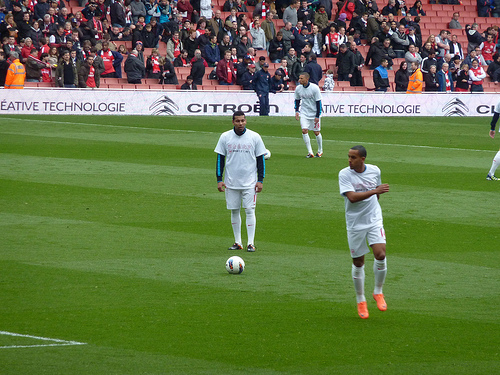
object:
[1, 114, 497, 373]
ground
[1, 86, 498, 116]
boundary board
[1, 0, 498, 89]
chairs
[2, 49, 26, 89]
guards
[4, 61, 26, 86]
dress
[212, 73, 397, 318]
soccer players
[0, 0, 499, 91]
crowd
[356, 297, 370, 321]
cleat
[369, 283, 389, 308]
cleat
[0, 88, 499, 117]
advertisements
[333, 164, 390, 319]
uniform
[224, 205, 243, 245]
leg sleeve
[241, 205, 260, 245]
leg sleeve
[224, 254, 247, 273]
ball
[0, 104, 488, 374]
scene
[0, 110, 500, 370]
pitch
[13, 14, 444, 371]
weather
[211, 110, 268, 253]
man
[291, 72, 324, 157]
man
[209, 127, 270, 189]
shirt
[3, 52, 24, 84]
man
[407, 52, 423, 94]
man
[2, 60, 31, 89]
coat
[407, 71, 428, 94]
coat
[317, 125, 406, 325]
man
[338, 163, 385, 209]
shirt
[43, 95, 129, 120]
word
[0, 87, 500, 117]
wall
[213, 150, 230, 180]
stripes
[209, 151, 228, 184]
shirt sleeve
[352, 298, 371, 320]
shoe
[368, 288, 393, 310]
shoe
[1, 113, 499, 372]
grass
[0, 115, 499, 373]
field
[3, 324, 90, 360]
lines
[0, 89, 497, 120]
field barrier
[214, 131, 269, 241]
uniform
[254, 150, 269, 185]
shirt sleeve